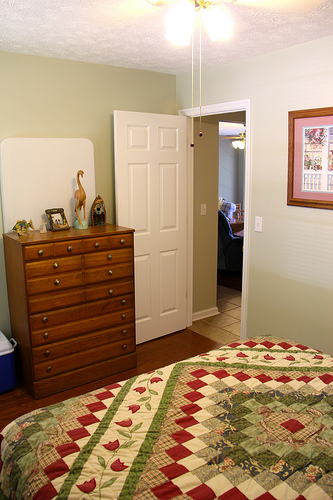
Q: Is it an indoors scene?
A: Yes, it is indoors.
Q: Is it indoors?
A: Yes, it is indoors.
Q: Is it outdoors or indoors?
A: It is indoors.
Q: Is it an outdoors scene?
A: No, it is indoors.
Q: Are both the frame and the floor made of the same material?
A: Yes, both the frame and the floor are made of wood.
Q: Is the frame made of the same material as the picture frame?
A: Yes, both the frame and the picture frame are made of wood.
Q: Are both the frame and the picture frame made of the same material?
A: Yes, both the frame and the picture frame are made of wood.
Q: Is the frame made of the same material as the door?
A: Yes, both the frame and the door are made of wood.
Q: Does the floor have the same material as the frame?
A: Yes, both the floor and the frame are made of wood.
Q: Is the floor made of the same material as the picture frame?
A: Yes, both the floor and the picture frame are made of wood.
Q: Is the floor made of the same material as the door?
A: Yes, both the floor and the door are made of wood.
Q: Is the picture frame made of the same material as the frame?
A: Yes, both the picture frame and the frame are made of wood.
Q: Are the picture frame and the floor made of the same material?
A: Yes, both the picture frame and the floor are made of wood.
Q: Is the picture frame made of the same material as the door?
A: Yes, both the picture frame and the door are made of wood.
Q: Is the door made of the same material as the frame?
A: Yes, both the door and the frame are made of wood.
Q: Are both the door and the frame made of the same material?
A: Yes, both the door and the frame are made of wood.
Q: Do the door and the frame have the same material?
A: Yes, both the door and the frame are made of wood.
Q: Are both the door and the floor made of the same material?
A: Yes, both the door and the floor are made of wood.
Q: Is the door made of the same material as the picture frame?
A: Yes, both the door and the picture frame are made of wood.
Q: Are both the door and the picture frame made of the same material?
A: Yes, both the door and the picture frame are made of wood.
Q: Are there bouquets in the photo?
A: No, there are no bouquets.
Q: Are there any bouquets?
A: No, there are no bouquets.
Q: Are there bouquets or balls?
A: No, there are no bouquets or balls.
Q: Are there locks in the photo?
A: No, there are no locks.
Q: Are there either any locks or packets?
A: No, there are no locks or packets.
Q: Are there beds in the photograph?
A: Yes, there is a bed.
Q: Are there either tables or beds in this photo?
A: Yes, there is a bed.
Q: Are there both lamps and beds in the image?
A: Yes, there are both a bed and a lamp.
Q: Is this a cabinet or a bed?
A: This is a bed.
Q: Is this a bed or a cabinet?
A: This is a bed.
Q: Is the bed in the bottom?
A: Yes, the bed is in the bottom of the image.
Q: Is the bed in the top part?
A: No, the bed is in the bottom of the image.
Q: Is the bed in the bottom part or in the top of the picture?
A: The bed is in the bottom of the image.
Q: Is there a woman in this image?
A: No, there are no women.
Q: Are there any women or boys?
A: No, there are no women or boys.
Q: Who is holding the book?
A: The man is holding the book.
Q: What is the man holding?
A: The man is holding the book.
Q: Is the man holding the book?
A: Yes, the man is holding the book.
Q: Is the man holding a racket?
A: No, the man is holding the book.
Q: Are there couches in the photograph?
A: No, there are no couches.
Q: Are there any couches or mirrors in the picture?
A: No, there are no couches or mirrors.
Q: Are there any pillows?
A: No, there are no pillows.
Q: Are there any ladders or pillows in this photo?
A: No, there are no pillows or ladders.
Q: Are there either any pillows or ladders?
A: No, there are no pillows or ladders.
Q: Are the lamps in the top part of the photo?
A: Yes, the lamps are in the top of the image.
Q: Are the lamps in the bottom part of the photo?
A: No, the lamps are in the top of the image.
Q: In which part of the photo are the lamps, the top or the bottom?
A: The lamps are in the top of the image.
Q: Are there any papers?
A: No, there are no papers.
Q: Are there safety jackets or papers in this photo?
A: No, there are no papers or safety jackets.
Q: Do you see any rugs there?
A: No, there are no rugs.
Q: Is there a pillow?
A: No, there are no pillows.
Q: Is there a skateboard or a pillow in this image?
A: No, there are no pillows or skateboards.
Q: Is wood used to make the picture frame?
A: Yes, the picture frame is made of wood.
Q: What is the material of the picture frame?
A: The picture frame is made of wood.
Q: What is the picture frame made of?
A: The picture frame is made of wood.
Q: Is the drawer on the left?
A: Yes, the drawer is on the left of the image.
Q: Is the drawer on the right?
A: No, the drawer is on the left of the image.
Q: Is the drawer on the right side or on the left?
A: The drawer is on the left of the image.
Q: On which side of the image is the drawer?
A: The drawer is on the left of the image.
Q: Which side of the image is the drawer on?
A: The drawer is on the left of the image.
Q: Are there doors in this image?
A: Yes, there is a door.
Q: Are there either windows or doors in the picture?
A: Yes, there is a door.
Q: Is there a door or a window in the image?
A: Yes, there is a door.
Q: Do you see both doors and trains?
A: No, there is a door but no trains.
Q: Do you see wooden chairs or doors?
A: Yes, there is a wood door.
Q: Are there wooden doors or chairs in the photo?
A: Yes, there is a wood door.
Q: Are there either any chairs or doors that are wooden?
A: Yes, the door is wooden.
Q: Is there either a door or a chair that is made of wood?
A: Yes, the door is made of wood.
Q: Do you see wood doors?
A: Yes, there is a wood door.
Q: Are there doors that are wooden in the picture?
A: Yes, there is a wood door.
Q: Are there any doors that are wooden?
A: Yes, there is a door that is wooden.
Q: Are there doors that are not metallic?
A: Yes, there is a wooden door.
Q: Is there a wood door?
A: Yes, there is a door that is made of wood.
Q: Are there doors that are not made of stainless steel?
A: Yes, there is a door that is made of wood.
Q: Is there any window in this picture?
A: No, there are no windows.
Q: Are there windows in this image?
A: No, there are no windows.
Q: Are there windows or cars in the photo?
A: No, there are no windows or cars.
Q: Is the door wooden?
A: Yes, the door is wooden.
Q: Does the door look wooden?
A: Yes, the door is wooden.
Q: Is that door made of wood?
A: Yes, the door is made of wood.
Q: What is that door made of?
A: The door is made of wood.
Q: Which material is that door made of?
A: The door is made of wood.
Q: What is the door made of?
A: The door is made of wood.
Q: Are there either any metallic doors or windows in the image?
A: No, there is a door but it is wooden.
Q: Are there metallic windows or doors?
A: No, there is a door but it is wooden.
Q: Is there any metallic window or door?
A: No, there is a door but it is wooden.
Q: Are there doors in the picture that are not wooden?
A: No, there is a door but it is wooden.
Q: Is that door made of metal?
A: No, the door is made of wood.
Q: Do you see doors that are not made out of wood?
A: No, there is a door but it is made of wood.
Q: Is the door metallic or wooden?
A: The door is wooden.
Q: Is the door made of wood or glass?
A: The door is made of wood.